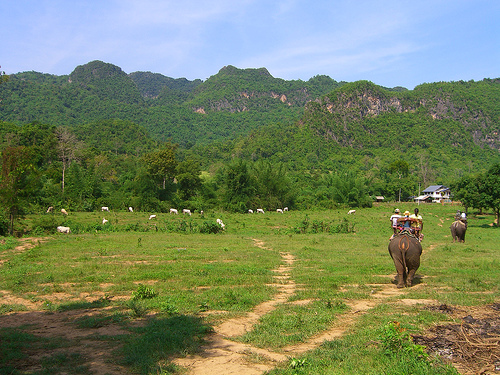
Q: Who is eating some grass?
A: A small herd of wild animals.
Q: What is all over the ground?
A: Grass.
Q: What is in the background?
A: Tall leafy trees.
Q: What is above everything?
A: The sky.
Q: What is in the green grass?
A: Paths.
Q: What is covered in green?
A: A tall mountain.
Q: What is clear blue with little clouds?
A: The sky.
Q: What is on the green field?
A: Bald spots.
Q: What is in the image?
A: Shadow of tree.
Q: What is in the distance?
A: Trees.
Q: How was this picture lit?
A: Natural light.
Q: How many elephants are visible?
A: Two.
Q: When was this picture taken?
A: Daytime.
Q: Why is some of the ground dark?
A: Shadow cast by the tree.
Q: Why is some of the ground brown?
A: The grass is dead.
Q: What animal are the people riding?
A: Elephant.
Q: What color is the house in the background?
A: White.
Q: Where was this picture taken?
A: On a safari.